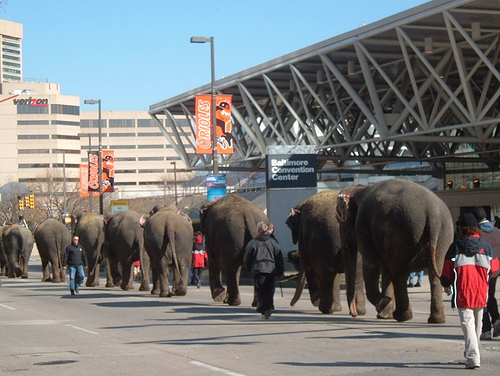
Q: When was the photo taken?
A: Daytime.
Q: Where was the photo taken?
A: Outdoors near a stadium.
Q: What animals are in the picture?
A: Elephants.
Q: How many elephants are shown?
A: Eight.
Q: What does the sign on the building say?
A: Verizon.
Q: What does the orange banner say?
A: Orioles.